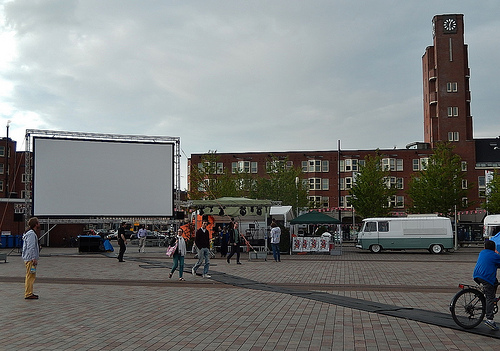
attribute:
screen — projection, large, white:
[32, 141, 179, 216]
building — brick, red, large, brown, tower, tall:
[185, 12, 500, 246]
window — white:
[446, 107, 453, 118]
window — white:
[313, 160, 322, 172]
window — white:
[247, 161, 258, 176]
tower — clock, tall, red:
[433, 10, 469, 144]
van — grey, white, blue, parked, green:
[356, 213, 456, 253]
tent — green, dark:
[286, 209, 343, 223]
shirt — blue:
[467, 252, 499, 280]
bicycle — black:
[448, 283, 499, 335]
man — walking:
[21, 216, 47, 303]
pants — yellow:
[21, 259, 40, 297]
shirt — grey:
[21, 231, 40, 263]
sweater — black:
[194, 230, 213, 250]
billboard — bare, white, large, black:
[22, 132, 185, 227]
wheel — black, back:
[449, 287, 487, 329]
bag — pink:
[164, 237, 179, 263]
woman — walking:
[166, 227, 189, 283]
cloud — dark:
[0, 9, 43, 115]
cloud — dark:
[1, 100, 74, 138]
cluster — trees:
[191, 136, 499, 216]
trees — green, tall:
[188, 132, 498, 207]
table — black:
[75, 238, 101, 252]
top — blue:
[75, 235, 100, 239]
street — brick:
[1, 237, 499, 347]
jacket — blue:
[473, 250, 499, 286]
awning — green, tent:
[284, 208, 342, 226]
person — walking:
[190, 214, 218, 281]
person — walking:
[165, 225, 189, 285]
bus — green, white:
[356, 211, 457, 255]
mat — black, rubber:
[299, 280, 409, 322]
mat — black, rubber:
[207, 260, 256, 296]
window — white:
[479, 174, 488, 183]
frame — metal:
[22, 134, 183, 227]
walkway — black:
[102, 250, 499, 341]